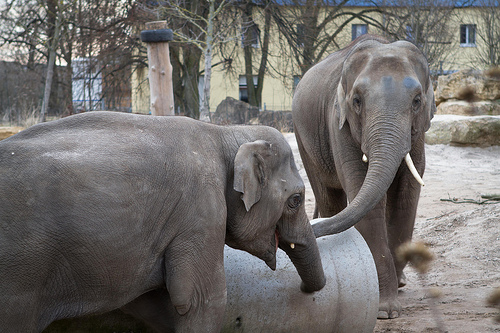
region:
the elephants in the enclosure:
[0, 33, 437, 331]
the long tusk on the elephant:
[404, 149, 426, 187]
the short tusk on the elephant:
[362, 153, 367, 163]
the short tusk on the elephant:
[290, 242, 295, 248]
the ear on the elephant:
[230, 139, 272, 212]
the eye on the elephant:
[413, 94, 420, 105]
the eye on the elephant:
[351, 95, 361, 106]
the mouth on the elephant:
[273, 223, 287, 272]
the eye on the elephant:
[292, 195, 299, 204]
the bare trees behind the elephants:
[1, 1, 496, 140]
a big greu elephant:
[298, 10, 495, 200]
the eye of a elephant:
[344, 82, 376, 124]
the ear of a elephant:
[220, 91, 322, 213]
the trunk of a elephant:
[313, 125, 425, 242]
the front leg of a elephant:
[339, 170, 417, 311]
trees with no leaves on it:
[135, 5, 407, 91]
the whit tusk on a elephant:
[377, 139, 449, 206]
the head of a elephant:
[339, 12, 494, 147]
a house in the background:
[201, 0, 365, 123]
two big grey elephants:
[71, 14, 474, 321]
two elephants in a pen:
[7, 4, 497, 331]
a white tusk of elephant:
[398, 145, 430, 190]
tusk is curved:
[397, 140, 428, 187]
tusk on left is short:
[351, 145, 377, 168]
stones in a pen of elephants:
[429, 56, 499, 156]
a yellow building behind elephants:
[181, 5, 494, 140]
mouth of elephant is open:
[260, 213, 305, 280]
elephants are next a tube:
[0, 24, 443, 331]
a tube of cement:
[220, 195, 384, 331]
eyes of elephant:
[346, 75, 425, 122]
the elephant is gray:
[257, 25, 437, 303]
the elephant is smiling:
[194, 84, 331, 323]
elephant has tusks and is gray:
[286, 35, 440, 320]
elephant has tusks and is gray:
[0, 96, 327, 331]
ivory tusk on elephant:
[404, 148, 426, 189]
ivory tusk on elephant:
[361, 152, 368, 164]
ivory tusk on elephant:
[286, 243, 297, 253]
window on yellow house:
[348, 21, 367, 43]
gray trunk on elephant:
[301, 110, 411, 232]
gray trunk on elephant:
[290, 221, 325, 294]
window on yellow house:
[458, 23, 475, 43]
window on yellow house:
[239, 74, 262, 101]